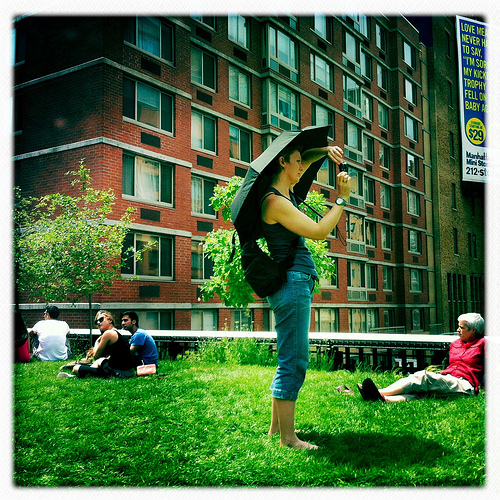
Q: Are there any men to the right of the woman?
A: Yes, there is a man to the right of the woman.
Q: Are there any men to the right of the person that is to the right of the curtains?
A: Yes, there is a man to the right of the woman.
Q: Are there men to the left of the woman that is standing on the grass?
A: No, the man is to the right of the woman.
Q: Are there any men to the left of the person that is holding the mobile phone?
A: No, the man is to the right of the woman.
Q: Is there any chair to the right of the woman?
A: No, there is a man to the right of the woman.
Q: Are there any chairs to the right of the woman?
A: No, there is a man to the right of the woman.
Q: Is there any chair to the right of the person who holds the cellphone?
A: No, there is a man to the right of the woman.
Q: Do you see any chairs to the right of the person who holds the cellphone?
A: No, there is a man to the right of the woman.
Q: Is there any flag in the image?
A: No, there are no flags.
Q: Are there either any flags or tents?
A: No, there are no flags or tents.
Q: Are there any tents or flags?
A: No, there are no flags or tents.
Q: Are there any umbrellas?
A: Yes, there is an umbrella.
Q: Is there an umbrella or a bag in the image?
A: Yes, there is an umbrella.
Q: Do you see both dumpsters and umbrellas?
A: No, there is an umbrella but no dumpsters.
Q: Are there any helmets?
A: No, there are no helmets.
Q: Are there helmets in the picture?
A: No, there are no helmets.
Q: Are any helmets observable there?
A: No, there are no helmets.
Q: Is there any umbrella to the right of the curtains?
A: Yes, there is an umbrella to the right of the curtains.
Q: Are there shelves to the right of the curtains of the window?
A: No, there is an umbrella to the right of the curtains.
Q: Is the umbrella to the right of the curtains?
A: Yes, the umbrella is to the right of the curtains.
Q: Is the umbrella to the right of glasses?
A: No, the umbrella is to the right of the curtains.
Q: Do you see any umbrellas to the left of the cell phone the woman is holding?
A: Yes, there is an umbrella to the left of the cellphone.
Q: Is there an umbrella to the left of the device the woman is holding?
A: Yes, there is an umbrella to the left of the cellphone.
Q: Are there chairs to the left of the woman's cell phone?
A: No, there is an umbrella to the left of the mobile phone.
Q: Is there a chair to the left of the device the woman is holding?
A: No, there is an umbrella to the left of the mobile phone.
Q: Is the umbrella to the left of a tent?
A: No, the umbrella is to the left of a cell phone.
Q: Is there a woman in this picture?
A: Yes, there is a woman.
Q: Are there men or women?
A: Yes, there is a woman.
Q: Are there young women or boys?
A: Yes, there is a young woman.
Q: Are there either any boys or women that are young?
A: Yes, the woman is young.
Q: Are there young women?
A: Yes, there is a young woman.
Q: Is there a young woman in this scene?
A: Yes, there is a young woman.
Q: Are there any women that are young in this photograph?
A: Yes, there is a young woman.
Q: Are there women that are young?
A: Yes, there is a woman that is young.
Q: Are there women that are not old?
A: Yes, there is an young woman.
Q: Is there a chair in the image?
A: No, there are no chairs.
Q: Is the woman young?
A: Yes, the woman is young.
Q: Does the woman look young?
A: Yes, the woman is young.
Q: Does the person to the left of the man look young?
A: Yes, the woman is young.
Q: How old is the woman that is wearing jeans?
A: The woman is young.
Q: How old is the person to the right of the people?
A: The woman is young.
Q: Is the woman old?
A: No, the woman is young.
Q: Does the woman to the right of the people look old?
A: No, the woman is young.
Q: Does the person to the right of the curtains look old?
A: No, the woman is young.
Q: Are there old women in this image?
A: No, there is a woman but she is young.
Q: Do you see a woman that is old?
A: No, there is a woman but she is young.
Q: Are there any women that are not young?
A: No, there is a woman but she is young.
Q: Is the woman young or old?
A: The woman is young.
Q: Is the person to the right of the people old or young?
A: The woman is young.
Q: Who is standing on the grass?
A: The woman is standing on the grass.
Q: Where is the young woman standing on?
A: The woman is standing on the grass.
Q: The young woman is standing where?
A: The woman is standing on the grass.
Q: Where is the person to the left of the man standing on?
A: The woman is standing on the grass.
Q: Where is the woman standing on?
A: The woman is standing on the grass.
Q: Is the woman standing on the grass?
A: Yes, the woman is standing on the grass.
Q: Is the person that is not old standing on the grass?
A: Yes, the woman is standing on the grass.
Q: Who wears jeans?
A: The woman wears jeans.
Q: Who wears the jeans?
A: The woman wears jeans.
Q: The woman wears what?
A: The woman wears jeans.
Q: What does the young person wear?
A: The woman wears jeans.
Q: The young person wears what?
A: The woman wears jeans.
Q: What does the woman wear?
A: The woman wears jeans.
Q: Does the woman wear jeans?
A: Yes, the woman wears jeans.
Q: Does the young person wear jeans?
A: Yes, the woman wears jeans.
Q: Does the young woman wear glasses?
A: No, the woman wears jeans.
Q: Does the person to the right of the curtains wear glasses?
A: No, the woman wears jeans.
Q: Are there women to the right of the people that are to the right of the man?
A: Yes, there is a woman to the right of the people.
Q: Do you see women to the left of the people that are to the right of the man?
A: No, the woman is to the right of the people.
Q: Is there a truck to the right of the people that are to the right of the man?
A: No, there is a woman to the right of the people.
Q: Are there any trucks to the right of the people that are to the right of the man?
A: No, there is a woman to the right of the people.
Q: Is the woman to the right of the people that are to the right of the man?
A: Yes, the woman is to the right of the people.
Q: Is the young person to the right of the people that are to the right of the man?
A: Yes, the woman is to the right of the people.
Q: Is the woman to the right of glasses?
A: No, the woman is to the right of the people.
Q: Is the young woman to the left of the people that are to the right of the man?
A: No, the woman is to the right of the people.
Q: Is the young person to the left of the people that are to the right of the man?
A: No, the woman is to the right of the people.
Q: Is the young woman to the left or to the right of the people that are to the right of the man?
A: The woman is to the right of the people.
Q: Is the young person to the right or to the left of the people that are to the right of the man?
A: The woman is to the right of the people.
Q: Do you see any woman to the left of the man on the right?
A: Yes, there is a woman to the left of the man.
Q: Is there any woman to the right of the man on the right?
A: No, the woman is to the left of the man.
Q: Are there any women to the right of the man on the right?
A: No, the woman is to the left of the man.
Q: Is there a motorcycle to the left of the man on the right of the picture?
A: No, there is a woman to the left of the man.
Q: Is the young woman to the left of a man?
A: Yes, the woman is to the left of a man.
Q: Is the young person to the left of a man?
A: Yes, the woman is to the left of a man.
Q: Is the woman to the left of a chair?
A: No, the woman is to the left of a man.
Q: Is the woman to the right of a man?
A: No, the woman is to the left of a man.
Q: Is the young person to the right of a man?
A: No, the woman is to the left of a man.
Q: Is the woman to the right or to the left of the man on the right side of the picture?
A: The woman is to the left of the man.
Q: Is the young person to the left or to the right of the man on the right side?
A: The woman is to the left of the man.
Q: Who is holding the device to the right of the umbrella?
A: The woman is holding the cell phone.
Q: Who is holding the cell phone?
A: The woman is holding the cell phone.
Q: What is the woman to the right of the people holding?
A: The woman is holding the mobile phone.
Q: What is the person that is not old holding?
A: The woman is holding the mobile phone.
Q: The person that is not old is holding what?
A: The woman is holding the mobile phone.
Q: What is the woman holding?
A: The woman is holding the mobile phone.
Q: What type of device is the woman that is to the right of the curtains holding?
A: The woman is holding the cell phone.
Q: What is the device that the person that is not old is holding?
A: The device is a cell phone.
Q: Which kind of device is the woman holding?
A: The woman is holding the cell phone.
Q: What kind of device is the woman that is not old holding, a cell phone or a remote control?
A: The woman is holding a cell phone.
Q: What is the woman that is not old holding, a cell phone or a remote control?
A: The woman is holding a cell phone.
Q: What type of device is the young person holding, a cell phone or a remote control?
A: The woman is holding a cell phone.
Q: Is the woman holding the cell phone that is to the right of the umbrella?
A: Yes, the woman is holding the cell phone.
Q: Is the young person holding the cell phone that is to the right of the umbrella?
A: Yes, the woman is holding the cell phone.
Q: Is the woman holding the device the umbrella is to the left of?
A: Yes, the woman is holding the cell phone.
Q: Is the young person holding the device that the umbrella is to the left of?
A: Yes, the woman is holding the cell phone.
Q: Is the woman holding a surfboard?
A: No, the woman is holding the cell phone.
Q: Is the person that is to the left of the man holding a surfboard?
A: No, the woman is holding the cell phone.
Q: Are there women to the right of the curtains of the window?
A: Yes, there is a woman to the right of the curtains.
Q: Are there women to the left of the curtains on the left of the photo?
A: No, the woman is to the right of the curtains.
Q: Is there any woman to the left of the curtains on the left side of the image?
A: No, the woman is to the right of the curtains.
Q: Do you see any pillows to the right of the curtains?
A: No, there is a woman to the right of the curtains.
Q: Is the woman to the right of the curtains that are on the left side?
A: Yes, the woman is to the right of the curtains.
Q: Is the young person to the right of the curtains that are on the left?
A: Yes, the woman is to the right of the curtains.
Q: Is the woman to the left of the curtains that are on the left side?
A: No, the woman is to the right of the curtains.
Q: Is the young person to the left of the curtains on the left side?
A: No, the woman is to the right of the curtains.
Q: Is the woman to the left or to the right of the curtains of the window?
A: The woman is to the right of the curtains.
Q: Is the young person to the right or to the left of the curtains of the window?
A: The woman is to the right of the curtains.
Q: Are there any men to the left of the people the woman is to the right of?
A: Yes, there is a man to the left of the people.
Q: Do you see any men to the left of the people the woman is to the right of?
A: Yes, there is a man to the left of the people.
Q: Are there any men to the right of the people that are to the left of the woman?
A: No, the man is to the left of the people.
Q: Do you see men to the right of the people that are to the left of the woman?
A: No, the man is to the left of the people.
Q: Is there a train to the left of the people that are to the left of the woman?
A: No, there is a man to the left of the people.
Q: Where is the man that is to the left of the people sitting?
A: The man is sitting in the grass.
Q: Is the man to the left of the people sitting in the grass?
A: Yes, the man is sitting in the grass.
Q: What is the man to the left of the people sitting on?
A: The man is sitting on the grass.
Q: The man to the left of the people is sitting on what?
A: The man is sitting on the grass.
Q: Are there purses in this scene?
A: Yes, there is a purse.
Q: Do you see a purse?
A: Yes, there is a purse.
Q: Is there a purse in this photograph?
A: Yes, there is a purse.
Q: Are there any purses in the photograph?
A: Yes, there is a purse.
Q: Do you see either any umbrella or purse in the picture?
A: Yes, there is a purse.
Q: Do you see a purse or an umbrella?
A: Yes, there is a purse.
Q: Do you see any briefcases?
A: No, there are no briefcases.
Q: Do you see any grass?
A: Yes, there is grass.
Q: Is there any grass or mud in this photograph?
A: Yes, there is grass.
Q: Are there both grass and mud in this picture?
A: No, there is grass but no mud.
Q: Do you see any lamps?
A: No, there are no lamps.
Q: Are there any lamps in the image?
A: No, there are no lamps.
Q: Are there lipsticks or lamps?
A: No, there are no lamps or lipsticks.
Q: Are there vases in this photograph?
A: No, there are no vases.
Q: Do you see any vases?
A: No, there are no vases.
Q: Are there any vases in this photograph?
A: No, there are no vases.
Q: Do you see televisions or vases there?
A: No, there are no vases or televisions.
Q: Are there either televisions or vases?
A: No, there are no vases or televisions.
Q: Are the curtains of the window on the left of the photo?
A: Yes, the curtains are on the left of the image.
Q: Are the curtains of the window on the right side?
A: No, the curtains are on the left of the image.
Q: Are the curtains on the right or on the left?
A: The curtains are on the left of the image.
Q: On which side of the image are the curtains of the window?
A: The curtains are on the left of the image.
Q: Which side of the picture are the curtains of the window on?
A: The curtains are on the left of the image.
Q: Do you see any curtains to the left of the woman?
A: Yes, there are curtains to the left of the woman.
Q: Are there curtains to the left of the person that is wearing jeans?
A: Yes, there are curtains to the left of the woman.